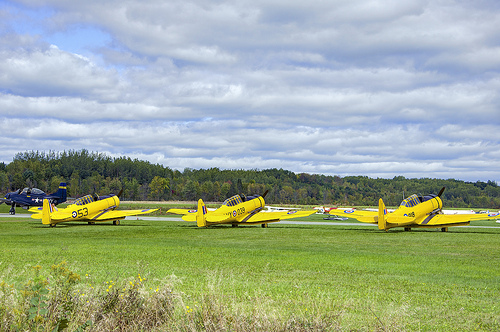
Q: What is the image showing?
A: It is showing a field.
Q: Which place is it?
A: It is a field.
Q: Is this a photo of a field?
A: Yes, it is showing a field.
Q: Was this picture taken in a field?
A: Yes, it was taken in a field.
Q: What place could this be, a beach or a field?
A: It is a field.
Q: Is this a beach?
A: No, it is a field.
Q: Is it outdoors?
A: Yes, it is outdoors.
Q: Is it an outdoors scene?
A: Yes, it is outdoors.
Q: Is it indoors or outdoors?
A: It is outdoors.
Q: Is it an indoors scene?
A: No, it is outdoors.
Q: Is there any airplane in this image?
A: Yes, there is an airplane.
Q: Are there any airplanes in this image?
A: Yes, there is an airplane.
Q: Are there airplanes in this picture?
A: Yes, there is an airplane.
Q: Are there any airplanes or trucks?
A: Yes, there is an airplane.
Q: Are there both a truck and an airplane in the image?
A: No, there is an airplane but no trucks.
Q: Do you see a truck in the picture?
A: No, there are no trucks.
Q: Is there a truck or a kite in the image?
A: No, there are no trucks or kites.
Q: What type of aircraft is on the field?
A: The aircraft is an airplane.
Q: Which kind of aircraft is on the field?
A: The aircraft is an airplane.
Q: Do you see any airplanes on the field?
A: Yes, there is an airplane on the field.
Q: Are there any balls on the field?
A: No, there is an airplane on the field.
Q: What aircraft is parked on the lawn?
A: The aircraft is an airplane.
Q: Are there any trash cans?
A: No, there are no trash cans.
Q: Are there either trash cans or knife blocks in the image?
A: No, there are no trash cans or knife blocks.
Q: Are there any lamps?
A: No, there are no lamps.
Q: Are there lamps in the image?
A: No, there are no lamps.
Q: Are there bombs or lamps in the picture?
A: No, there are no lamps or bombs.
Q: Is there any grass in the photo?
A: Yes, there is grass.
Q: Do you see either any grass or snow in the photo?
A: Yes, there is grass.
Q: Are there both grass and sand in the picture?
A: No, there is grass but no sand.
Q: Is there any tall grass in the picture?
A: Yes, there is tall grass.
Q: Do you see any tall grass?
A: Yes, there is tall grass.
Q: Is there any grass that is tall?
A: Yes, there is grass that is tall.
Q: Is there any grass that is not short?
A: Yes, there is tall grass.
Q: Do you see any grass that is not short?
A: Yes, there is tall grass.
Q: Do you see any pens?
A: No, there are no pens.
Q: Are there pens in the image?
A: No, there are no pens.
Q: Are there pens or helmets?
A: No, there are no pens or helmets.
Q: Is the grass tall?
A: Yes, the grass is tall.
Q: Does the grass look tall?
A: Yes, the grass is tall.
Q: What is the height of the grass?
A: The grass is tall.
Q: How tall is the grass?
A: The grass is tall.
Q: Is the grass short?
A: No, the grass is tall.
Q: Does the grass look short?
A: No, the grass is tall.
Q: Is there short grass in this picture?
A: No, there is grass but it is tall.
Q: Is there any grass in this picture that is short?
A: No, there is grass but it is tall.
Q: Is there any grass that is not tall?
A: No, there is grass but it is tall.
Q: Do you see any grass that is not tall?
A: No, there is grass but it is tall.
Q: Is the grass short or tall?
A: The grass is tall.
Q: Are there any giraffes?
A: No, there are no giraffes.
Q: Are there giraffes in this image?
A: No, there are no giraffes.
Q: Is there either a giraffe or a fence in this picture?
A: No, there are no giraffes or fences.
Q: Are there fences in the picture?
A: No, there are no fences.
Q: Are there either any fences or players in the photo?
A: No, there are no fences or players.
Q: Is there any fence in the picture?
A: No, there are no fences.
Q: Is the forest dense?
A: Yes, the forest is dense.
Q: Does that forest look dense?
A: Yes, the forest is dense.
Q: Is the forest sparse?
A: No, the forest is dense.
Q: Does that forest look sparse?
A: No, the forest is dense.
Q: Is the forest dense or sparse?
A: The forest is dense.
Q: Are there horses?
A: No, there are no horses.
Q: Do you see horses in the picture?
A: No, there are no horses.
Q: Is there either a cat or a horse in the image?
A: No, there are no horses or cats.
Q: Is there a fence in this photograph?
A: No, there are no fences.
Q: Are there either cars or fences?
A: No, there are no fences or cars.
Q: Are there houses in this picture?
A: No, there are no houses.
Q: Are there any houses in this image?
A: No, there are no houses.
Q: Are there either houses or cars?
A: No, there are no houses or cars.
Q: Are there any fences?
A: No, there are no fences.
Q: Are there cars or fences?
A: No, there are no fences or cars.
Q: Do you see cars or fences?
A: No, there are no fences or cars.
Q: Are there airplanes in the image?
A: Yes, there is an airplane.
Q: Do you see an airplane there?
A: Yes, there is an airplane.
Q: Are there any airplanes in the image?
A: Yes, there is an airplane.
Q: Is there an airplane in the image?
A: Yes, there is an airplane.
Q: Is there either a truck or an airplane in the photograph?
A: Yes, there is an airplane.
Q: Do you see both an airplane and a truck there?
A: No, there is an airplane but no trucks.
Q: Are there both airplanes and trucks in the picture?
A: No, there is an airplane but no trucks.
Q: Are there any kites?
A: No, there are no kites.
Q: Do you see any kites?
A: No, there are no kites.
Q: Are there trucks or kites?
A: No, there are no kites or trucks.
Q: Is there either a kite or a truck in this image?
A: No, there are no kites or trucks.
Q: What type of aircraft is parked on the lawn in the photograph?
A: The aircraft is an airplane.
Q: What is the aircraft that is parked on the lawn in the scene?
A: The aircraft is an airplane.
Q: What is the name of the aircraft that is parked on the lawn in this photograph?
A: The aircraft is an airplane.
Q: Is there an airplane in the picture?
A: Yes, there is an airplane.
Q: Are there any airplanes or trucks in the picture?
A: Yes, there is an airplane.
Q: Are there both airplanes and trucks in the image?
A: No, there is an airplane but no trucks.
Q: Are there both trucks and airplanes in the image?
A: No, there is an airplane but no trucks.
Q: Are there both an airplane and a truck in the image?
A: No, there is an airplane but no trucks.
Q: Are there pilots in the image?
A: No, there are no pilots.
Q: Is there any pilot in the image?
A: No, there are no pilots.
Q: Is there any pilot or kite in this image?
A: No, there are no pilots or kites.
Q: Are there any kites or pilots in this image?
A: No, there are no pilots or kites.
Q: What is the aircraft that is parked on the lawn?
A: The aircraft is an airplane.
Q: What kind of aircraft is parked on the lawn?
A: The aircraft is an airplane.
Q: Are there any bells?
A: No, there are no bells.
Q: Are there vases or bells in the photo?
A: No, there are no bells or vases.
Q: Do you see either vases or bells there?
A: No, there are no bells or vases.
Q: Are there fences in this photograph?
A: No, there are no fences.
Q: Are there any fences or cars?
A: No, there are no fences or cars.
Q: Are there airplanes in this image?
A: Yes, there is an airplane.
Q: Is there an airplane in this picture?
A: Yes, there is an airplane.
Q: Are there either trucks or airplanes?
A: Yes, there is an airplane.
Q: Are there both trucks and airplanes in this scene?
A: No, there is an airplane but no trucks.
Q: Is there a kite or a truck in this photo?
A: No, there are no kites or trucks.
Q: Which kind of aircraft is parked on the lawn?
A: The aircraft is an airplane.